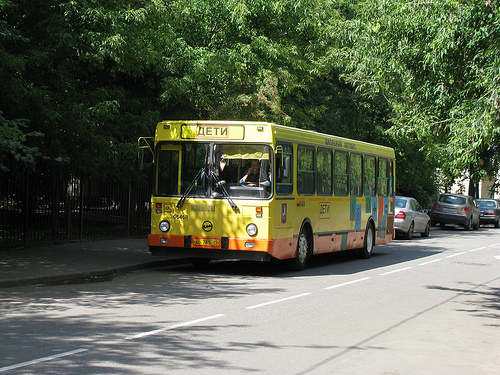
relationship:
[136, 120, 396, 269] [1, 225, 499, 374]
bus parked on street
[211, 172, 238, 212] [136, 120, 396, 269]
wiper on front of bus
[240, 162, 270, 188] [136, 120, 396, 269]
person driving bus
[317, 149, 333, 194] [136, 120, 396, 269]
window on side of bus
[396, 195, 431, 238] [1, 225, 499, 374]
car parked on street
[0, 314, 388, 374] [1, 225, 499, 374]
shadow on street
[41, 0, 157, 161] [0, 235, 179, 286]
tree along sidewalk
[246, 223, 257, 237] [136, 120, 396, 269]
light on bus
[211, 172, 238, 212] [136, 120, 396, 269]
wiper on bus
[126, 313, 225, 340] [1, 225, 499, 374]
line on street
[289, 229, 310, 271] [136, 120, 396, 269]
wheel on bus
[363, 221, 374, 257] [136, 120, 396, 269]
wheel on bus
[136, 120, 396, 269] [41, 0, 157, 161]
bus in front of tree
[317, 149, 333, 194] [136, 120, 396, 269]
window on bus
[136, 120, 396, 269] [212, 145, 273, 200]
bus has windshield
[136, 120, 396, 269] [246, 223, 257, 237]
bus has light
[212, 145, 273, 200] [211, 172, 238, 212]
windshield has wiper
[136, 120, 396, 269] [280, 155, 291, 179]
bus has mirror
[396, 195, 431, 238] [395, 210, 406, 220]
car has light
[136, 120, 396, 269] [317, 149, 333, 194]
bus has window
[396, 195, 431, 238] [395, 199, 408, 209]
car has windshield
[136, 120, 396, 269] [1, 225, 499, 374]
bus along street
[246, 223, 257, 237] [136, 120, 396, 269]
light on front of bus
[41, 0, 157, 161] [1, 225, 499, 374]
tree over street